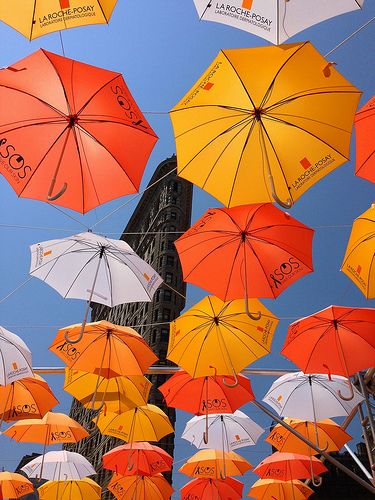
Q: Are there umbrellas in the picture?
A: Yes, there is an umbrella.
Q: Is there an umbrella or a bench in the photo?
A: Yes, there is an umbrella.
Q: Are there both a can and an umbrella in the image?
A: No, there is an umbrella but no cans.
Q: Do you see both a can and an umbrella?
A: No, there is an umbrella but no cans.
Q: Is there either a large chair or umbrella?
A: Yes, there is a large umbrella.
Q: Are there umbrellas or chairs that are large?
A: Yes, the umbrella is large.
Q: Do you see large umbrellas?
A: Yes, there is a large umbrella.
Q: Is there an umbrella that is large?
A: Yes, there is an umbrella that is large.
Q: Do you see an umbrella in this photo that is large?
A: Yes, there is an umbrella that is large.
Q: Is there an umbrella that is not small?
A: Yes, there is a large umbrella.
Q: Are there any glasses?
A: No, there are no glasses.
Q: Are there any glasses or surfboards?
A: No, there are no glasses or surfboards.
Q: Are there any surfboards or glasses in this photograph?
A: No, there are no glasses or surfboards.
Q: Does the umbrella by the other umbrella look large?
A: Yes, the umbrella is large.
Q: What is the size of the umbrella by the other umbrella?
A: The umbrella is large.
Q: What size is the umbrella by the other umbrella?
A: The umbrella is large.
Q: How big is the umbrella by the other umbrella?
A: The umbrella is large.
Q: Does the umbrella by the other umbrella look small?
A: No, the umbrella is large.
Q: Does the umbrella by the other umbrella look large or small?
A: The umbrella is large.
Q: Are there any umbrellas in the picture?
A: Yes, there is an umbrella.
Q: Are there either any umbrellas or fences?
A: Yes, there is an umbrella.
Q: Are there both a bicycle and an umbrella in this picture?
A: No, there is an umbrella but no bicycles.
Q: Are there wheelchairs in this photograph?
A: No, there are no wheelchairs.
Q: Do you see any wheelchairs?
A: No, there are no wheelchairs.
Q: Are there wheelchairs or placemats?
A: No, there are no wheelchairs or placemats.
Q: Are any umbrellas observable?
A: Yes, there is an umbrella.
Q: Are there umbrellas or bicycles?
A: Yes, there is an umbrella.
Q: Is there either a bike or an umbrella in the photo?
A: Yes, there is an umbrella.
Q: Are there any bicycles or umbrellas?
A: Yes, there is an umbrella.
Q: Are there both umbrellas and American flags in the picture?
A: No, there is an umbrella but no American flags.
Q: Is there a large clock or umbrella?
A: Yes, there is a large umbrella.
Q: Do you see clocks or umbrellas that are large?
A: Yes, the umbrella is large.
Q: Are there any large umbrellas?
A: Yes, there is a large umbrella.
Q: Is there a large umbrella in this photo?
A: Yes, there is a large umbrella.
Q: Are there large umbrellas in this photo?
A: Yes, there is a large umbrella.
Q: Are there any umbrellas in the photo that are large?
A: Yes, there is an umbrella that is large.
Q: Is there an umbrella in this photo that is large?
A: Yes, there is an umbrella that is large.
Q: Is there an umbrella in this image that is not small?
A: Yes, there is a large umbrella.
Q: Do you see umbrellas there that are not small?
A: Yes, there is a large umbrella.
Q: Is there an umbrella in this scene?
A: Yes, there is an umbrella.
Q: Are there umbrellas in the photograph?
A: Yes, there is an umbrella.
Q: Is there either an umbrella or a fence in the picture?
A: Yes, there is an umbrella.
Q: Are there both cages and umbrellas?
A: No, there is an umbrella but no cages.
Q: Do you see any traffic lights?
A: No, there are no traffic lights.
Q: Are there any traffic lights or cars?
A: No, there are no traffic lights or cars.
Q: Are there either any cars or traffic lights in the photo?
A: No, there are no traffic lights or cars.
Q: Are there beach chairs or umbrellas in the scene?
A: Yes, there is an umbrella.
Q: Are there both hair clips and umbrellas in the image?
A: No, there is an umbrella but no hair clips.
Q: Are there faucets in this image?
A: No, there are no faucets.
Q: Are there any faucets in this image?
A: No, there are no faucets.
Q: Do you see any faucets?
A: No, there are no faucets.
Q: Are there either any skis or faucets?
A: No, there are no faucets or skis.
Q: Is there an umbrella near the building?
A: Yes, there is an umbrella near the building.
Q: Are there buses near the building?
A: No, there is an umbrella near the building.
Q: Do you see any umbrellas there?
A: Yes, there is an umbrella.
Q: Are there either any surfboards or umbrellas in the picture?
A: Yes, there is an umbrella.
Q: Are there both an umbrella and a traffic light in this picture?
A: No, there is an umbrella but no traffic lights.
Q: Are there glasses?
A: No, there are no glasses.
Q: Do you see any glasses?
A: No, there are no glasses.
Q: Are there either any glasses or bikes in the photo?
A: No, there are no glasses or bikes.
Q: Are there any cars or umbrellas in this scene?
A: Yes, there is an umbrella.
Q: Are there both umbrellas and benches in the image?
A: No, there is an umbrella but no benches.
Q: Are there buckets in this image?
A: No, there are no buckets.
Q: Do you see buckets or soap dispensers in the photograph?
A: No, there are no buckets or soap dispensers.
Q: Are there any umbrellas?
A: Yes, there is an umbrella.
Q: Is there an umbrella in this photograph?
A: Yes, there is an umbrella.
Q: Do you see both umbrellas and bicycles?
A: No, there is an umbrella but no bicycles.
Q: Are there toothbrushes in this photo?
A: No, there are no toothbrushes.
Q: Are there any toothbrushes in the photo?
A: No, there are no toothbrushes.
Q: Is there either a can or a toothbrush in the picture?
A: No, there are no toothbrushes or cans.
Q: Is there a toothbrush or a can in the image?
A: No, there are no toothbrushes or cans.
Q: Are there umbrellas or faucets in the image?
A: Yes, there is an umbrella.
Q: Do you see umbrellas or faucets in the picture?
A: Yes, there is an umbrella.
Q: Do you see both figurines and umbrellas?
A: No, there is an umbrella but no figurines.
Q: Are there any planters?
A: No, there are no planters.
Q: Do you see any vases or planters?
A: No, there are no planters or vases.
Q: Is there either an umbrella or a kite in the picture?
A: Yes, there is an umbrella.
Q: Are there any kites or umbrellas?
A: Yes, there is an umbrella.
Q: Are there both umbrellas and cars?
A: No, there is an umbrella but no cars.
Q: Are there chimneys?
A: No, there are no chimneys.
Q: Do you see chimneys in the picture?
A: No, there are no chimneys.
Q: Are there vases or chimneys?
A: No, there are no chimneys or vases.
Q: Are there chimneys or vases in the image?
A: No, there are no chimneys or vases.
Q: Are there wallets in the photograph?
A: No, there are no wallets.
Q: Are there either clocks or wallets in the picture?
A: No, there are no wallets or clocks.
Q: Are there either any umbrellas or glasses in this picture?
A: Yes, there is an umbrella.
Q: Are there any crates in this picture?
A: No, there are no crates.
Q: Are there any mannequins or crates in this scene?
A: No, there are no crates or mannequins.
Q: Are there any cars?
A: No, there are no cars.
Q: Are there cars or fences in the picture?
A: No, there are no cars or fences.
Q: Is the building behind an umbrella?
A: Yes, the building is behind an umbrella.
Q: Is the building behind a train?
A: No, the building is behind an umbrella.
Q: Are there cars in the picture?
A: No, there are no cars.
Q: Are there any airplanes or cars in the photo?
A: No, there are no cars or airplanes.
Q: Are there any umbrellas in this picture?
A: Yes, there is an umbrella.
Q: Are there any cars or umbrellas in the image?
A: Yes, there is an umbrella.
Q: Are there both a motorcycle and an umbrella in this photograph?
A: No, there is an umbrella but no motorcycles.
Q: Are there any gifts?
A: No, there are no gifts.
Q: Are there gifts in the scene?
A: No, there are no gifts.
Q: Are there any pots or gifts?
A: No, there are no gifts or pots.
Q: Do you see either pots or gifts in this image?
A: No, there are no gifts or pots.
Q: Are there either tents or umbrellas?
A: Yes, there is an umbrella.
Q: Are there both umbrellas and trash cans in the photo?
A: No, there is an umbrella but no trash cans.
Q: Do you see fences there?
A: No, there are no fences.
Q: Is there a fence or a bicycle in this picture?
A: No, there are no fences or bicycles.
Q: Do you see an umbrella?
A: Yes, there is an umbrella.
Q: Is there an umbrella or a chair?
A: Yes, there is an umbrella.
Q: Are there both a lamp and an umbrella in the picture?
A: No, there is an umbrella but no lamps.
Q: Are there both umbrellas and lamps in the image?
A: No, there is an umbrella but no lamps.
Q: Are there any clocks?
A: No, there are no clocks.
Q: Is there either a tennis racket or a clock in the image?
A: No, there are no clocks or rackets.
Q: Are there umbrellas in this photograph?
A: Yes, there is an umbrella.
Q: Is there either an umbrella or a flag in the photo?
A: Yes, there is an umbrella.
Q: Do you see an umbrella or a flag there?
A: Yes, there is an umbrella.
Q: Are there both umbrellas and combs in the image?
A: No, there is an umbrella but no combs.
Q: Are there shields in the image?
A: No, there are no shields.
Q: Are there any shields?
A: No, there are no shields.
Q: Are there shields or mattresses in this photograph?
A: No, there are no shields or mattresses.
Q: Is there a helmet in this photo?
A: No, there are no helmets.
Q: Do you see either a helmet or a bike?
A: No, there are no helmets or bikes.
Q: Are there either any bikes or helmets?
A: No, there are no helmets or bikes.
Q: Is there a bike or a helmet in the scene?
A: No, there are no helmets or bikes.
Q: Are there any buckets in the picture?
A: No, there are no buckets.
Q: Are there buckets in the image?
A: No, there are no buckets.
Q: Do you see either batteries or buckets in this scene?
A: No, there are no buckets or batteries.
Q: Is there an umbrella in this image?
A: Yes, there is an umbrella.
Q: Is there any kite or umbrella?
A: Yes, there is an umbrella.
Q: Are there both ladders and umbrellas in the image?
A: No, there is an umbrella but no ladders.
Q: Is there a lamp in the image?
A: No, there are no lamps.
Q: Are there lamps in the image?
A: No, there are no lamps.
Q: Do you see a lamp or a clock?
A: No, there are no lamps or clocks.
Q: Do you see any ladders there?
A: No, there are no ladders.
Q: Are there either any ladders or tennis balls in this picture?
A: No, there are no ladders or tennis balls.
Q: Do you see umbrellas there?
A: Yes, there is an umbrella.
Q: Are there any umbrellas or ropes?
A: Yes, there is an umbrella.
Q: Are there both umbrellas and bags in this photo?
A: No, there is an umbrella but no bags.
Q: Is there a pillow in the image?
A: No, there are no pillows.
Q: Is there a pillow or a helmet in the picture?
A: No, there are no pillows or helmets.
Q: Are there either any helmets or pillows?
A: No, there are no pillows or helmets.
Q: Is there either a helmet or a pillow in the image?
A: No, there are no pillows or helmets.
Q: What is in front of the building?
A: The umbrella is in front of the building.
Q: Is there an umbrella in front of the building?
A: Yes, there is an umbrella in front of the building.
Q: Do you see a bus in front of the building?
A: No, there is an umbrella in front of the building.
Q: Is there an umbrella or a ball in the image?
A: Yes, there is an umbrella.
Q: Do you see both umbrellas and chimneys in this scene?
A: No, there is an umbrella but no chimneys.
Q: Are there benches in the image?
A: No, there are no benches.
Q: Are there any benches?
A: No, there are no benches.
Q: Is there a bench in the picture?
A: No, there are no benches.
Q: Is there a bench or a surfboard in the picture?
A: No, there are no benches or surfboards.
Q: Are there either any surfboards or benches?
A: No, there are no benches or surfboards.